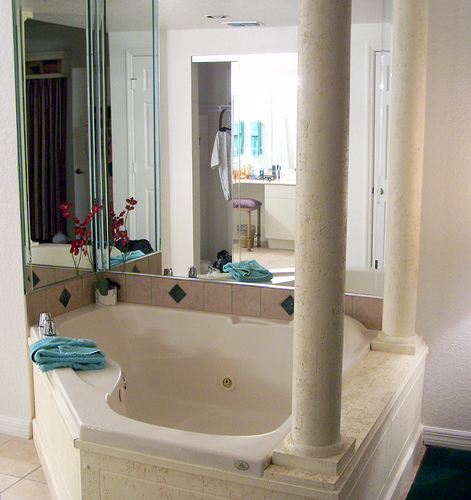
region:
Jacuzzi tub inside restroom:
[25, 252, 376, 486]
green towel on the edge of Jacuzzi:
[23, 330, 109, 376]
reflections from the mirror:
[184, 38, 332, 290]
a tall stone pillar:
[263, 19, 392, 486]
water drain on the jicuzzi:
[210, 364, 240, 394]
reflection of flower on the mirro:
[54, 178, 148, 277]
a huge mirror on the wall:
[14, 6, 406, 314]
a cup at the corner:
[74, 266, 126, 304]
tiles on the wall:
[158, 276, 205, 311]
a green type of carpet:
[432, 450, 468, 482]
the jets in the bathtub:
[220, 376, 238, 390]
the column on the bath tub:
[265, 0, 361, 473]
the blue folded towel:
[31, 334, 107, 372]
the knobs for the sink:
[32, 305, 50, 345]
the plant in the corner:
[55, 194, 127, 302]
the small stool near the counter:
[231, 191, 264, 252]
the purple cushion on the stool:
[229, 193, 259, 207]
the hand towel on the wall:
[245, 119, 265, 151]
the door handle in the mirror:
[74, 165, 84, 179]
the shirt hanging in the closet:
[206, 122, 233, 200]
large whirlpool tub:
[27, 278, 382, 479]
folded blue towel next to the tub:
[24, 327, 112, 374]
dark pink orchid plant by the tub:
[54, 190, 128, 303]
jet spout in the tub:
[216, 375, 238, 393]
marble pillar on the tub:
[276, 0, 354, 475]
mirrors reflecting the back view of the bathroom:
[17, 0, 376, 300]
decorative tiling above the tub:
[26, 273, 299, 322]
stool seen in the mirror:
[230, 190, 265, 251]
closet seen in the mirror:
[193, 61, 230, 270]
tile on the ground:
[1, 430, 58, 495]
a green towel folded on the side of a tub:
[16, 322, 109, 377]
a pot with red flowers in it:
[69, 182, 131, 309]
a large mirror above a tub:
[0, 38, 319, 325]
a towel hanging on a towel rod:
[228, 108, 275, 168]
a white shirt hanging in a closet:
[205, 98, 232, 203]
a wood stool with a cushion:
[229, 189, 262, 250]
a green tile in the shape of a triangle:
[159, 283, 193, 306]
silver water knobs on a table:
[32, 301, 59, 360]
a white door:
[362, 39, 386, 273]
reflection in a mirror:
[88, 34, 303, 312]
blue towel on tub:
[31, 340, 106, 387]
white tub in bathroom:
[68, 296, 353, 498]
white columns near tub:
[260, 9, 431, 489]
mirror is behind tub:
[132, 13, 367, 289]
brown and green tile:
[23, 278, 378, 331]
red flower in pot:
[37, 206, 104, 273]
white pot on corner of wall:
[95, 266, 126, 309]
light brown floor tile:
[6, 436, 43, 498]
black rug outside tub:
[415, 436, 464, 498]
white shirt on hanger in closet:
[203, 118, 247, 202]